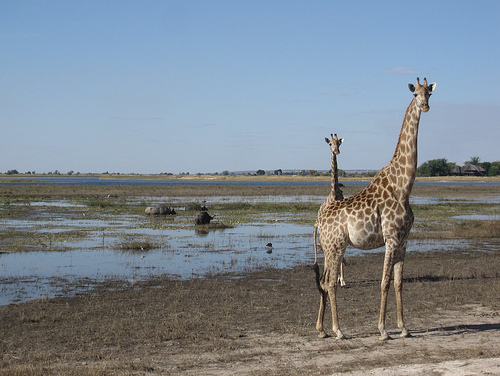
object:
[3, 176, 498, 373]
swamp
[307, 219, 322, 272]
tail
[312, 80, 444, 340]
giraffe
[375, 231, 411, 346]
legs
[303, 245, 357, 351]
legs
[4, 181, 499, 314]
marsh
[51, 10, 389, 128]
clouds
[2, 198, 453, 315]
water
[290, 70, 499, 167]
clouds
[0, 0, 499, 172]
sky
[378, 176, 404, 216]
brown spots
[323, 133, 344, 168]
head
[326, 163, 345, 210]
giraffe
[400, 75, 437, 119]
giraffe head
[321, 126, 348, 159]
giraffe head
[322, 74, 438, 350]
tan giraffe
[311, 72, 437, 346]
giraffe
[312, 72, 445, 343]
giraffe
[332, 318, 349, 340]
hoof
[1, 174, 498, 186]
blue water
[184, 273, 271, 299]
grass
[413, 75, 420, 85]
horn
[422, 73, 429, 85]
horn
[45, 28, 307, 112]
sky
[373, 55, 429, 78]
clouds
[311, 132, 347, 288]
giraffe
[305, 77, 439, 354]
giraffe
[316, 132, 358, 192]
giraffe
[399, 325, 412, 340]
hoof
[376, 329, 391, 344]
hoof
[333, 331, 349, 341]
hoof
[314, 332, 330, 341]
hoof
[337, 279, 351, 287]
hoof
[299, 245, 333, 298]
tail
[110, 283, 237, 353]
grass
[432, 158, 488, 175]
house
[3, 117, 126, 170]
clouds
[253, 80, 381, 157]
clouds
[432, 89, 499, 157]
clouds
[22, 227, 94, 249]
weeds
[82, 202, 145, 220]
weeds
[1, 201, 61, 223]
weeds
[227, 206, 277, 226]
weeds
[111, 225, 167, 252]
weeds